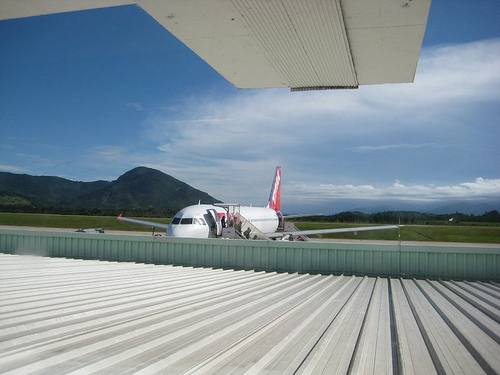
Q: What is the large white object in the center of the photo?
A: Plane.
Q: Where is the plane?
A: On the tarmac.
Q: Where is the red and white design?
A: On the tail of the plane.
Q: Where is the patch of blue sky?
A: On the upper left.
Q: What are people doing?
A: Disembarking.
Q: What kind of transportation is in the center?
A: Airplane.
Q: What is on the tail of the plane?
A: The airline logo.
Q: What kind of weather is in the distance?
A: Clouds and storms.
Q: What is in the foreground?
A: Corrugated metal roofing.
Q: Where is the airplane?
A: On the tarmac.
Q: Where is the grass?
A: Behind the plane.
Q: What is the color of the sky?
A: White and blue.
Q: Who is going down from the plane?
A: People.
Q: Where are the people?
A: On the plane.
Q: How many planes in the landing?
A: One.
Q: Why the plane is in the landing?
A: To unload people.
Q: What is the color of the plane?
A: White.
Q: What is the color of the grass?
A: Green.